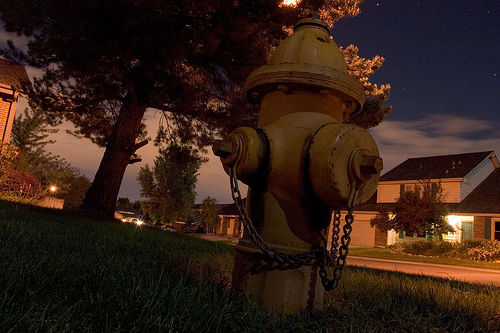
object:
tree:
[0, 0, 393, 228]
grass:
[137, 264, 184, 311]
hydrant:
[213, 9, 385, 320]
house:
[373, 148, 499, 256]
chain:
[318, 168, 366, 292]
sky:
[391, 15, 489, 104]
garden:
[345, 243, 499, 269]